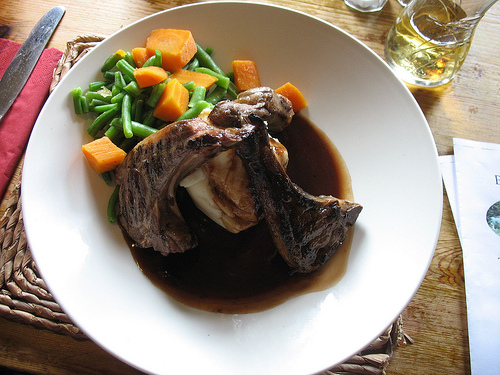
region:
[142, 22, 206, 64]
orange slice of carrot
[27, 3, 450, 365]
food on white dinner plate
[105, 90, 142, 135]
green beans on plate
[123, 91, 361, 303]
piece of cooked meat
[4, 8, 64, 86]
tip of silver knife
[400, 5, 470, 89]
yellow liquid in a glass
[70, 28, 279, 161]
mix of orange and green vegies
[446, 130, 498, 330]
white piece of paper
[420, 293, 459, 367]
brown wooden table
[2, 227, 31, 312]
pad for hot items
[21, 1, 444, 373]
White bowl of food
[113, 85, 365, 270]
Two pork chops on a plate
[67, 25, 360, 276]
Pork chops and vegetables on gravy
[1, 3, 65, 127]
Silver scratched butter knife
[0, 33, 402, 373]
Brown wicker placemat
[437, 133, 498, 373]
Two papers on a table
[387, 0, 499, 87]
Glass of yellow liquid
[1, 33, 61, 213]
Folded burgundy paper napkin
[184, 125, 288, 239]
Scoop of mashed potatoes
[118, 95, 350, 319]
Full bowl of brown gravy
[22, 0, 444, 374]
A white dinner plate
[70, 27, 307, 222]
A serving of carrots and green beans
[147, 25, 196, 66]
A slice of carrot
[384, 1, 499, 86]
A drinking glass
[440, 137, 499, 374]
Part of a paper menu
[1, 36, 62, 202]
A red napkin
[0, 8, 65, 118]
The top of a butter knife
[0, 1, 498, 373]
A wooden table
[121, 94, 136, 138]
One green bean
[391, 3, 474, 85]
a glass on the table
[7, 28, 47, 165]
a red napkin on the table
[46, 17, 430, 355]
a plate of food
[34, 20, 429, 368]
a large white plate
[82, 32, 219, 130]
peas and carrots on the plate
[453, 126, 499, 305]
papers on the table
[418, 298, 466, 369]
the table under the plate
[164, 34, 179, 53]
the carrots are orange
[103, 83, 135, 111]
the green beans are green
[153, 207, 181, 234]
the meat is brown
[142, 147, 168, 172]
the meat has grill marks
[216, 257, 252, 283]
the sauce is brown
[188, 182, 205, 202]
the potatoes are white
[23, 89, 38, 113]
the napkin is red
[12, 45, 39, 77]
the knife is silver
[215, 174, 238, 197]
the sauce is on the potatoes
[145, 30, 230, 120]
Carrots in the bowl.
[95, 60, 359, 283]
Food in the bowl.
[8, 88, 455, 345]
The bowl is white.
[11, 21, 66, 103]
Knife on the red napkin.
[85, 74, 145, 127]
The green beans are green.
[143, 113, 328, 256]
Beef on top of the potatoes.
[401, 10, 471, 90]
A glass on the table.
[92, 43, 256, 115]
Carrots and string beans are mixed.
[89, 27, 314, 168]
orange carrot pieces on the plate